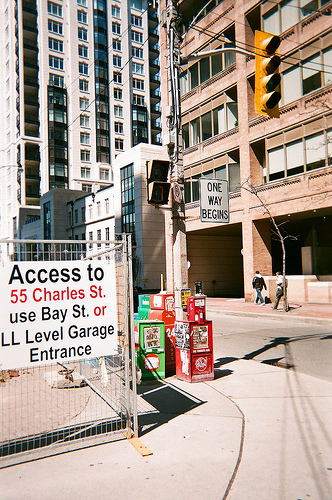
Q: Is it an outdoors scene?
A: Yes, it is outdoors.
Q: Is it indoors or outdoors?
A: It is outdoors.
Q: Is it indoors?
A: No, it is outdoors.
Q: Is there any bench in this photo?
A: No, there are no benches.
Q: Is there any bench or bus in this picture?
A: No, there are no benches or buses.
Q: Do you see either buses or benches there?
A: No, there are no benches or buses.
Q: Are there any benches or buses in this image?
A: No, there are no benches or buses.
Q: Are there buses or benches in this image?
A: No, there are no benches or buses.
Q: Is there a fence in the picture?
A: Yes, there is a fence.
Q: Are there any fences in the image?
A: Yes, there is a fence.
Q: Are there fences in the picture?
A: Yes, there is a fence.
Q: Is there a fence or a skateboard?
A: Yes, there is a fence.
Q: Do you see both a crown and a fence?
A: No, there is a fence but no crowns.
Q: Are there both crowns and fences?
A: No, there is a fence but no crowns.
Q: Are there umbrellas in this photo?
A: No, there are no umbrellas.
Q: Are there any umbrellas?
A: No, there are no umbrellas.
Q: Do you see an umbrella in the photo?
A: No, there are no umbrellas.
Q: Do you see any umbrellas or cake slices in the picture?
A: No, there are no umbrellas or cake slices.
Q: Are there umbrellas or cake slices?
A: No, there are no umbrellas or cake slices.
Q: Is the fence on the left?
A: Yes, the fence is on the left of the image.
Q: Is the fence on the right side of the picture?
A: No, the fence is on the left of the image.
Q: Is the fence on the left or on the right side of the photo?
A: The fence is on the left of the image.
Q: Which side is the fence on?
A: The fence is on the left of the image.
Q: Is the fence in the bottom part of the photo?
A: Yes, the fence is in the bottom of the image.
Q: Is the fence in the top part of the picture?
A: No, the fence is in the bottom of the image.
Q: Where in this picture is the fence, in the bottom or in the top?
A: The fence is in the bottom of the image.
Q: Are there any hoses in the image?
A: No, there are no hoses.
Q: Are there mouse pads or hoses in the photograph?
A: No, there are no hoses or mouse pads.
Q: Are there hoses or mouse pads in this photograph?
A: No, there are no hoses or mouse pads.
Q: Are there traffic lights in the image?
A: Yes, there is a traffic light.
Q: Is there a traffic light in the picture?
A: Yes, there is a traffic light.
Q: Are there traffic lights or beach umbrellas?
A: Yes, there is a traffic light.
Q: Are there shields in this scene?
A: No, there are no shields.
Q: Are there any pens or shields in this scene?
A: No, there are no shields or pens.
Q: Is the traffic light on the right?
A: Yes, the traffic light is on the right of the image.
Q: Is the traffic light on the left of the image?
A: No, the traffic light is on the right of the image.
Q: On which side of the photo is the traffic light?
A: The traffic light is on the right of the image.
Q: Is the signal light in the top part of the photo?
A: Yes, the signal light is in the top of the image.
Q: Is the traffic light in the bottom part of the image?
A: No, the traffic light is in the top of the image.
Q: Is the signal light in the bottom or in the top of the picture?
A: The signal light is in the top of the image.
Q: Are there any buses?
A: No, there are no buses.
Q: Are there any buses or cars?
A: No, there are no buses or cars.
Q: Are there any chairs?
A: No, there are no chairs.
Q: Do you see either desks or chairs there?
A: No, there are no chairs or desks.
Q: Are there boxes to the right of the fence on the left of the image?
A: Yes, there is a box to the right of the fence.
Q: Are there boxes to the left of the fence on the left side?
A: No, the box is to the right of the fence.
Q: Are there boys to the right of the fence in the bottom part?
A: No, there is a box to the right of the fence.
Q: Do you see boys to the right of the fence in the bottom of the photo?
A: No, there is a box to the right of the fence.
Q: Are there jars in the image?
A: No, there are no jars.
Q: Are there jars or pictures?
A: No, there are no jars or pictures.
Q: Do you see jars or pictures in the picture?
A: No, there are no jars or pictures.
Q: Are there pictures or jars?
A: No, there are no jars or pictures.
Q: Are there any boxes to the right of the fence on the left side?
A: Yes, there is a box to the right of the fence.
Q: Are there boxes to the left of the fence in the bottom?
A: No, the box is to the right of the fence.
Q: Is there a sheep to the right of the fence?
A: No, there is a box to the right of the fence.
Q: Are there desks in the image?
A: No, there are no desks.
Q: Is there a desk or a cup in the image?
A: No, there are no desks or cups.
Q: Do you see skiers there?
A: No, there are no skiers.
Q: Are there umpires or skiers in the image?
A: No, there are no skiers or umpires.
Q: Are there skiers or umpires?
A: No, there are no skiers or umpires.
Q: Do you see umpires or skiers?
A: No, there are no skiers or umpires.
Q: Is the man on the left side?
A: No, the man is on the right of the image.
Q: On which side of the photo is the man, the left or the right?
A: The man is on the right of the image.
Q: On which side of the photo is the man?
A: The man is on the right of the image.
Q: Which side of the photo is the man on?
A: The man is on the right of the image.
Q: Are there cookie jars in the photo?
A: No, there are no cookie jars.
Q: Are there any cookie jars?
A: No, there are no cookie jars.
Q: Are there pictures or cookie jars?
A: No, there are no cookie jars or pictures.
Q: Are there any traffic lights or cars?
A: Yes, there is a traffic light.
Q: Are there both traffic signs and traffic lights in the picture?
A: Yes, there are both a traffic light and a traffic sign.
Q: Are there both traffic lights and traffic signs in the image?
A: Yes, there are both a traffic light and a traffic sign.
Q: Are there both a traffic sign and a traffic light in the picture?
A: Yes, there are both a traffic light and a traffic sign.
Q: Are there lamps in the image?
A: No, there are no lamps.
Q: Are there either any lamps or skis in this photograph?
A: No, there are no lamps or skis.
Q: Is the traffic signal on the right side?
A: Yes, the traffic signal is on the right of the image.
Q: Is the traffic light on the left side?
A: No, the traffic light is on the right of the image.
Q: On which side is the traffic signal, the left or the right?
A: The traffic signal is on the right of the image.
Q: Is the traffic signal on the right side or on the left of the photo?
A: The traffic signal is on the right of the image.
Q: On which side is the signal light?
A: The signal light is on the right of the image.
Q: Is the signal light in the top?
A: Yes, the signal light is in the top of the image.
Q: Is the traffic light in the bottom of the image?
A: No, the traffic light is in the top of the image.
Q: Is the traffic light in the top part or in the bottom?
A: The traffic light is in the top of the image.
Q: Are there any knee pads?
A: No, there are no knee pads.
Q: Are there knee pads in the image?
A: No, there are no knee pads.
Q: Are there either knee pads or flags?
A: No, there are no knee pads or flags.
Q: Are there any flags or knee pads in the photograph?
A: No, there are no knee pads or flags.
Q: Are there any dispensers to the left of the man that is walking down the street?
A: Yes, there is a dispenser to the left of the man.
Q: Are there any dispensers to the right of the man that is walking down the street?
A: No, the dispenser is to the left of the man.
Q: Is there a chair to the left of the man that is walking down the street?
A: No, there is a dispenser to the left of the man.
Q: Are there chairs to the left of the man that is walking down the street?
A: No, there is a dispenser to the left of the man.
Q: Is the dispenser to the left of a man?
A: Yes, the dispenser is to the left of a man.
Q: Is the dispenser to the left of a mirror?
A: No, the dispenser is to the left of a man.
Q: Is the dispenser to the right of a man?
A: No, the dispenser is to the left of a man.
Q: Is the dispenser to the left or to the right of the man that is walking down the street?
A: The dispenser is to the left of the man.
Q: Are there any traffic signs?
A: Yes, there is a traffic sign.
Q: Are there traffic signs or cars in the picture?
A: Yes, there is a traffic sign.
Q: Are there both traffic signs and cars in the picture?
A: No, there is a traffic sign but no cars.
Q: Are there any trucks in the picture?
A: No, there are no trucks.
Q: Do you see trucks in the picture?
A: No, there are no trucks.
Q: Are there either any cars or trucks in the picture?
A: No, there are no trucks or cars.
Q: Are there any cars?
A: No, there are no cars.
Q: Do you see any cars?
A: No, there are no cars.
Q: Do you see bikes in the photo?
A: No, there are no bikes.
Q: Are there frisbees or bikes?
A: No, there are no bikes or frisbees.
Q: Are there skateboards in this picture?
A: No, there are no skateboards.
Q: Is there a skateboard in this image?
A: No, there are no skateboards.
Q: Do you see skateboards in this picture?
A: No, there are no skateboards.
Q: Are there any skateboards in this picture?
A: No, there are no skateboards.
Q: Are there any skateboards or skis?
A: No, there are no skateboards or skis.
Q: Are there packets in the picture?
A: No, there are no packets.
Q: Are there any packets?
A: No, there are no packets.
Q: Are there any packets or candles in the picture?
A: No, there are no packets or candles.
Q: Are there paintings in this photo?
A: No, there are no paintings.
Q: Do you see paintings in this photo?
A: No, there are no paintings.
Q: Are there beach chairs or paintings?
A: No, there are no paintings or beach chairs.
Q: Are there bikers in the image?
A: No, there are no bikers.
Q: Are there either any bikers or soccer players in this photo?
A: No, there are no bikers or soccer players.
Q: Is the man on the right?
A: Yes, the man is on the right of the image.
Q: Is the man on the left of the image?
A: No, the man is on the right of the image.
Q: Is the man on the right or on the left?
A: The man is on the right of the image.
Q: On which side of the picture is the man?
A: The man is on the right of the image.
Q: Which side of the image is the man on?
A: The man is on the right of the image.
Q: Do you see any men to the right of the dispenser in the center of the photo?
A: Yes, there is a man to the right of the dispenser.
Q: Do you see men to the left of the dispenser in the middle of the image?
A: No, the man is to the right of the dispenser.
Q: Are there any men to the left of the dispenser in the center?
A: No, the man is to the right of the dispenser.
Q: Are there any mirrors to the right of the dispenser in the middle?
A: No, there is a man to the right of the dispenser.